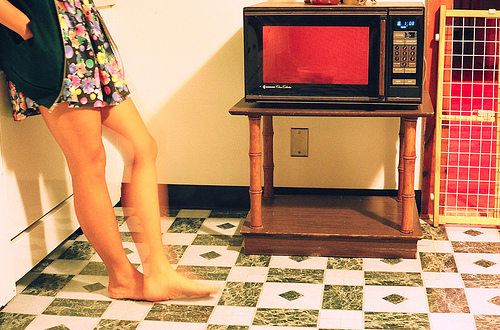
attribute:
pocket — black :
[14, 22, 49, 99]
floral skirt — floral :
[11, 6, 126, 122]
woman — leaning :
[5, 1, 223, 308]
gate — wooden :
[433, 4, 499, 231]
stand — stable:
[227, 95, 433, 260]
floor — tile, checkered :
[63, 179, 494, 326]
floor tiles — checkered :
[1, 209, 498, 329]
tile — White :
[361, 284, 431, 314]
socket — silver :
[287, 125, 311, 160]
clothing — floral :
[1, 0, 130, 115]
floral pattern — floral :
[16, 10, 136, 118]